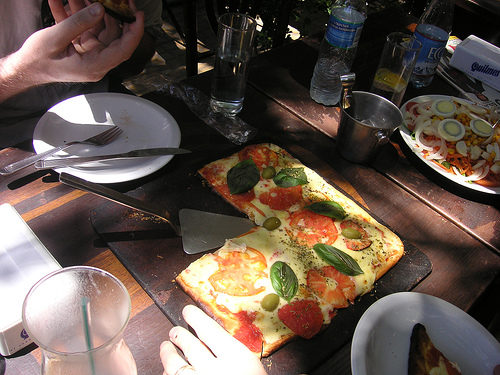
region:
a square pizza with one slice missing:
[170, 138, 409, 359]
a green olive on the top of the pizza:
[261, 288, 283, 312]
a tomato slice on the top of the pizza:
[211, 240, 272, 302]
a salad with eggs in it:
[396, 90, 498, 198]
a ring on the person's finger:
[166, 358, 192, 374]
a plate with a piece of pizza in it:
[347, 285, 497, 373]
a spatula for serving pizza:
[53, 167, 263, 262]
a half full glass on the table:
[209, 9, 264, 113]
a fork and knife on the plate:
[0, 118, 191, 193]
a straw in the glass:
[75, 292, 98, 374]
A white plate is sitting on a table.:
[29, 89, 184, 186]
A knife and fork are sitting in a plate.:
[0, 90, 195, 188]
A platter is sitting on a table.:
[85, 139, 435, 373]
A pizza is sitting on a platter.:
[175, 140, 407, 360]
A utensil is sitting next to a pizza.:
[52, 167, 259, 264]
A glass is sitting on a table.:
[18, 259, 141, 374]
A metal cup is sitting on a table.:
[326, 79, 406, 174]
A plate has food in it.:
[397, 87, 499, 197]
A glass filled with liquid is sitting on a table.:
[201, 7, 260, 125]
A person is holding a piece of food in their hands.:
[0, 0, 150, 107]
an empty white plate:
[30, 90, 180, 181]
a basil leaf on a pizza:
[270, 259, 296, 301]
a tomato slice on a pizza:
[276, 297, 325, 341]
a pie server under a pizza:
[57, 173, 260, 256]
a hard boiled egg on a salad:
[438, 117, 467, 142]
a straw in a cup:
[77, 295, 98, 374]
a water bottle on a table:
[310, 0, 368, 106]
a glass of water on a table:
[209, 15, 254, 114]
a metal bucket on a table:
[332, 88, 404, 168]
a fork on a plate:
[0, 122, 122, 175]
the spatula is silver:
[193, 216, 221, 239]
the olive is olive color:
[265, 297, 275, 308]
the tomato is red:
[306, 218, 324, 235]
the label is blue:
[333, 26, 344, 40]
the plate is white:
[367, 324, 388, 347]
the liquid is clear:
[224, 71, 236, 86]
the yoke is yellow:
[448, 124, 457, 133]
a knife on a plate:
[31, 143, 196, 169]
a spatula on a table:
[58, 170, 264, 252]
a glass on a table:
[20, 265, 136, 370]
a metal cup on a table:
[330, 85, 401, 162]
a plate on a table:
[350, 288, 498, 370]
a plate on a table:
[398, 93, 498, 194]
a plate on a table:
[31, 93, 179, 183]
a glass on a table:
[210, 10, 253, 116]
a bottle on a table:
[400, 1, 457, 97]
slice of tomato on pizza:
[207, 244, 270, 297]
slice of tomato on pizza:
[285, 207, 338, 248]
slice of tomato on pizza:
[305, 264, 355, 305]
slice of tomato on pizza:
[237, 146, 279, 170]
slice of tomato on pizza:
[259, 185, 307, 208]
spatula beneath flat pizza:
[58, 171, 256, 255]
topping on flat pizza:
[312, 241, 364, 276]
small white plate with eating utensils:
[30, 88, 185, 188]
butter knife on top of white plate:
[34, 142, 189, 171]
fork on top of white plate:
[0, 122, 125, 179]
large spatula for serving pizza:
[53, 169, 260, 257]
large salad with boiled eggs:
[397, 89, 498, 196]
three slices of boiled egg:
[430, 93, 495, 145]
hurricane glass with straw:
[17, 265, 138, 374]